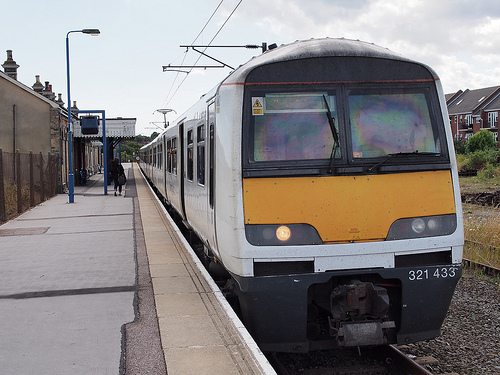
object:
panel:
[243, 168, 458, 245]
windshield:
[243, 83, 452, 177]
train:
[135, 37, 467, 350]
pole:
[66, 30, 82, 203]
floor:
[0, 162, 279, 375]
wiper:
[323, 93, 341, 174]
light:
[275, 225, 292, 241]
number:
[405, 266, 459, 281]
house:
[443, 85, 500, 150]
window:
[194, 124, 205, 185]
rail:
[375, 338, 435, 375]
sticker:
[251, 96, 263, 116]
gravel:
[391, 273, 500, 375]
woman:
[109, 157, 127, 196]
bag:
[117, 172, 128, 185]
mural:
[0, 177, 42, 219]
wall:
[1, 71, 67, 226]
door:
[206, 100, 219, 259]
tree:
[463, 129, 500, 181]